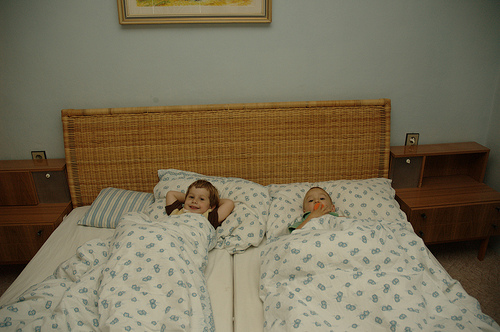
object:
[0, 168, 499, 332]
comforters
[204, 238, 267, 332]
mattress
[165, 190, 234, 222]
arms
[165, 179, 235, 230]
boy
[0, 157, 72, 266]
night stand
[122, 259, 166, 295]
designs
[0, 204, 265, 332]
blanket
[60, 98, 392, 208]
head board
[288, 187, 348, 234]
baby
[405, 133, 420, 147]
picture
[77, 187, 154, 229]
pillow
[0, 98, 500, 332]
bed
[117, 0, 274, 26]
frame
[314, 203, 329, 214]
binky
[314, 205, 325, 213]
mouth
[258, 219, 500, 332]
sheets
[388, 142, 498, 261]
cupboards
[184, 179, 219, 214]
head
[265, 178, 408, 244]
pillow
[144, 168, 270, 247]
pillow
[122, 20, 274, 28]
edge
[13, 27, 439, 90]
wall